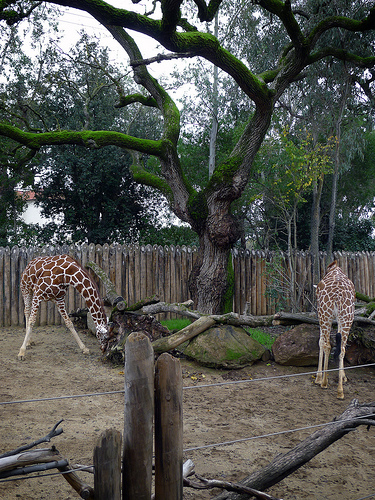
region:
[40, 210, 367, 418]
giraffes with their head down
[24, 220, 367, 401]
large giraffes with head down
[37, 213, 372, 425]
giraffes behind a fence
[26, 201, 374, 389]
two giraffes behind a fence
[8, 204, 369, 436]
giraffes behind a wooden fence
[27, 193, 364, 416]
two giraffes behind a wooden fence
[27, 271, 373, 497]
giraffes behind a wire fence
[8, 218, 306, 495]
two giraffes behind a wire fence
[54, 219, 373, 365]
an area with giraffes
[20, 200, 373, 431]
giraffes under a tree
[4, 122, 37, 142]
Moss growing on gree branch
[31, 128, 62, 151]
Moss growing on gree branch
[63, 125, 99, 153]
Moss growing on gree branch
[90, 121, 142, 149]
Moss growing on gree branch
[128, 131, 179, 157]
Moss growing on gree branch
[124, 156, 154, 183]
Moss growing on gree branch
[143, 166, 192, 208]
Moss growing on gree branch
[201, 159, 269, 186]
Moss growing on gree branch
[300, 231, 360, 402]
Giraffe in a field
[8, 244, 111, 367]
Giraffe in a field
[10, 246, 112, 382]
A giraffe leans his head on the rock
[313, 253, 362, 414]
The rear end of a giraffe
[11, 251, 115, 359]
The giraffe has orange and brown spots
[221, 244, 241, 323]
Moss is growing on the tree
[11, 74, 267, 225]
The tree branches have moss on them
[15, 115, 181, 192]
The moss on the tree is a green color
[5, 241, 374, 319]
A wooden fence is behind the tree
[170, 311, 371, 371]
Rocks are piled on the ground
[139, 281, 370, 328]
Branches are piled on the rocks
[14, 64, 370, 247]
Green trees are in the background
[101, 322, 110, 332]
The ears of the giraffe on the left.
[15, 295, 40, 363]
The front left leg of the giraffe on the left.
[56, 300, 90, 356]
The front right leg of the giraffe on the left.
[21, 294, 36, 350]
The back legs of the giraffe on the left.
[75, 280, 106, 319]
The neck of the giraffe on the left.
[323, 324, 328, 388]
The back left leg of the giraffe on the right.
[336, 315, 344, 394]
The back right leg of the giraffe on the right.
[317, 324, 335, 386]
The front leg of the giraffe on the right.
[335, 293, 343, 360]
The tail of the giraffe on the right.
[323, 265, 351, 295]
The back of the giraffe on the right.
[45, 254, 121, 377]
giraffe is sniffing the ground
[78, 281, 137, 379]
giraffe is sniffing the ground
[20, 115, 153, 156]
moss on the tree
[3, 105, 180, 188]
moss on the tree